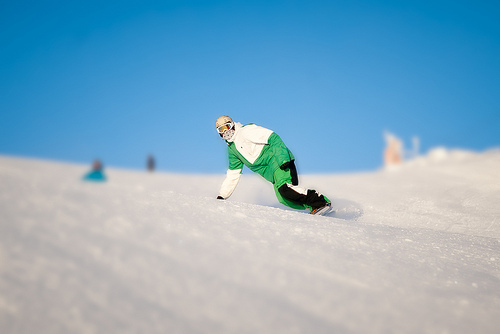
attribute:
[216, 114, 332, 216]
person — leaning, snowboarding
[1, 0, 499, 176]
sky — clear, blue, cloudless, crisp, bright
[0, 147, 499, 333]
snow — white, clean, fluffy, powdery, tightly packed, bright, out of focus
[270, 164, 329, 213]
pants — white, black, green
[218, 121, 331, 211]
snow suit — green, white, black, gree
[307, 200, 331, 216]
snowboard — white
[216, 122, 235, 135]
ski goggles — white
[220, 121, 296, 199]
ski jacket — green, white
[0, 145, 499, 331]
mountain — snowy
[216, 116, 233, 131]
helmet — gold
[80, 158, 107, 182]
person — out of focus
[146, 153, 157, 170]
figure — out of focus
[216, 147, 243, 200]
arm — extended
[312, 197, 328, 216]
boot — gray, orange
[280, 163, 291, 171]
glove — black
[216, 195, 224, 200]
glove — black